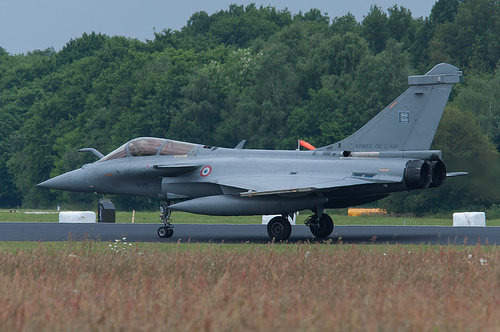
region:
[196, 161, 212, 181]
logo on an aircraft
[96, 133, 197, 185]
cock pit of a jet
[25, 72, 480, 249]
grey jet plane on a runway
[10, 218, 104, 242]
black pavement of a runway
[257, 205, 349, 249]
two wheels of a jet's landing gear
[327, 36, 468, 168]
grey tail end of a jet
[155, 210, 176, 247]
front landing gear of a jet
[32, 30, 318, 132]
row of trees along the runway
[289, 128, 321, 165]
orange flapping wind sock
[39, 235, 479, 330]
dry grass along the runway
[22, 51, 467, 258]
jet on ground in front of trees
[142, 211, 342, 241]
small wheel in front of larger ones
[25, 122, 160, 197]
pointy nose of jet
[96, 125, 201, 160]
curbed top of cockpit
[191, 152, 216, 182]
red, white and blue circle on grey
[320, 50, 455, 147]
curve in front of wing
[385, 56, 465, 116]
bar across the top of tail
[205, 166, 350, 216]
triangular shape of wing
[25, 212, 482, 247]
smooth grey surface of paved ground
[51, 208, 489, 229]
white blocks along edge of path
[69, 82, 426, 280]
Gray jet on ground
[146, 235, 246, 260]
Green grass next to runway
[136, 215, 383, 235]
Black wheels on landing gear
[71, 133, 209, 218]
Clear windshield on front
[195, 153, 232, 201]
Red and white bulls eye on side of jet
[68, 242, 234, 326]
Brown grass next to green grass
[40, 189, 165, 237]
White concrete blocks on side of runway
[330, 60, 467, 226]
Tail of plane is gray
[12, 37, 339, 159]
Large trees behind jet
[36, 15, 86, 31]
Sky is grayish blue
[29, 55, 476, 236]
a fighter on the runway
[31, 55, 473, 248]
a fighter on the tarmac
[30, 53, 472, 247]
a fighter on the ground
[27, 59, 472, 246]
a fighter on the taxiway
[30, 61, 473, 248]
a jet on the runway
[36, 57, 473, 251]
a jet on the ground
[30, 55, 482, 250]
a jet on the tarmac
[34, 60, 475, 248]
a jet on the taxiway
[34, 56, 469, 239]
a jet with minimal markings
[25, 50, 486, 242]
a grey airplane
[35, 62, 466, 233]
Small gray jet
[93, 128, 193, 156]
Front window of the jet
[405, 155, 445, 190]
Black exhaust pipes of the jet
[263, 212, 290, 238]
Left back wheel of the jet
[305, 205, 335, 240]
Right back wheel of the jet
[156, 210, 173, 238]
Front wheel of the jet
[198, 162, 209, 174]
Target logo on the jet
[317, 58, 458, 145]
Tail of the jet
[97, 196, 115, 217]
Small garbage can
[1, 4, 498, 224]
Forest land